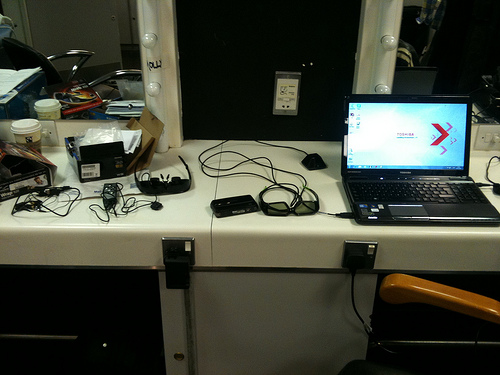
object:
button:
[357, 186, 359, 191]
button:
[367, 185, 373, 188]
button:
[389, 184, 397, 186]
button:
[410, 186, 420, 191]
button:
[439, 190, 447, 194]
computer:
[341, 93, 500, 228]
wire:
[351, 268, 399, 356]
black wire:
[198, 138, 315, 207]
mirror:
[0, 0, 146, 131]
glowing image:
[347, 102, 466, 170]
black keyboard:
[347, 180, 490, 204]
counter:
[0, 139, 500, 272]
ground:
[400, 75, 435, 104]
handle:
[363, 269, 498, 336]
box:
[64, 107, 164, 183]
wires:
[197, 138, 308, 207]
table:
[12, 132, 497, 279]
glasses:
[134, 154, 192, 195]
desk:
[2, 129, 499, 374]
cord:
[198, 132, 328, 219]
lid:
[10, 118, 42, 134]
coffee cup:
[10, 118, 43, 152]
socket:
[341, 239, 379, 270]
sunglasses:
[259, 186, 320, 216]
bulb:
[142, 33, 157, 49]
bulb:
[381, 36, 397, 51]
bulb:
[374, 83, 392, 94]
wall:
[132, 0, 404, 154]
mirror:
[386, 1, 499, 98]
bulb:
[146, 82, 162, 97]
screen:
[345, 101, 467, 169]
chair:
[354, 272, 500, 374]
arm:
[378, 271, 497, 320]